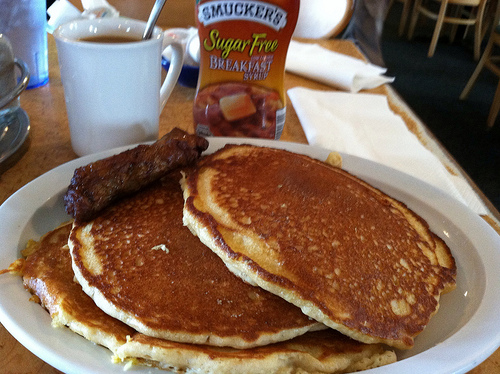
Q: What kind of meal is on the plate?
A: Breakfast.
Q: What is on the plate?
A: Sausage and pancakes.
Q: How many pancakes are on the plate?
A: 3.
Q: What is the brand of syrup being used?
A: Smucker's.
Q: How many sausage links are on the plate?
A: Two.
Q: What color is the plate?
A: White.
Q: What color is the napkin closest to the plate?
A: White.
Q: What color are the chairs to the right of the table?
A: Brown.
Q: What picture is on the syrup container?
A: A pancake with butter and syrup.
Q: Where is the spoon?
A: In the white cup.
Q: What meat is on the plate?
A: Sausage.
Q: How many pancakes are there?
A: Three.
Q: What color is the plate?
A: White.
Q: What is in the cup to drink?
A: Coffee.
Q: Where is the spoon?
A: In the coffee cup.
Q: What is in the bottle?
A: Breakfast syrup.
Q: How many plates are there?
A: One.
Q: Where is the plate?
A: On the table.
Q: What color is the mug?
A: White.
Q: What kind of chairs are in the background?
A: Wooden.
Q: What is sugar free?
A: The pancake syrup.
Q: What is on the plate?
A: Pancakes and sausage.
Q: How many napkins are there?
A: Two.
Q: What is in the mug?
A: Coffee.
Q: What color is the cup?
A: White.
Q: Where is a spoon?
A: In the coffee.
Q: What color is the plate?
A: White.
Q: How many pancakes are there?
A: Three.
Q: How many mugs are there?
A: One.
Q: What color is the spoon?
A: Silver.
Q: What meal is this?
A: Breakfast.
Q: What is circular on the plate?
A: Pancakes.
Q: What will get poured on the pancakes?
A: Syrup.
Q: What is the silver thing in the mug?
A: Spoon.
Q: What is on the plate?
A: Pancakes and sausage.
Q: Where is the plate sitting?
A: On a table.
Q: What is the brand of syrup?
A: Smucker's.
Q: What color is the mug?
A: White.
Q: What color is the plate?
A: White.